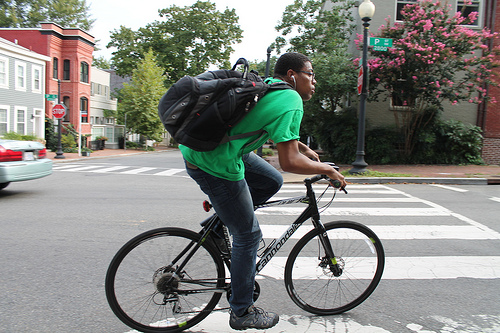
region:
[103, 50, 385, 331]
Boy riding bicycle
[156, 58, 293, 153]
Backpack on the boy's back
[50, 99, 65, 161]
Stop sign on curb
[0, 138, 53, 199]
Rear end of car going down the street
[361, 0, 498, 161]
Pink flowering plant by sidewalk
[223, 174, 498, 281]
White lines designating crosswalk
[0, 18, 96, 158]
Pink building next to grey building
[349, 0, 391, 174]
Street lamp with street sign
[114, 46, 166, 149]
Tree along the curb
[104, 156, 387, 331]
Black bike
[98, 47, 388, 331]
Male riding a bike on the road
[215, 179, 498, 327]
Crosswalk the male is driving over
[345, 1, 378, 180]
Old fashioned street lamp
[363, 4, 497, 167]
Pink flowering tree next to the building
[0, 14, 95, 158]
Red brick building on the left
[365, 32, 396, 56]
Green street sign with P on it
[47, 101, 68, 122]
Stop sign on the left side of the road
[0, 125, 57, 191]
Back of a silver car on the street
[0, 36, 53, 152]
Grey 2 story building with white trim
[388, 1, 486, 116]
Three windows behind the flowering pink tree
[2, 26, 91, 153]
a large red colored building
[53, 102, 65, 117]
a red and white STOP sign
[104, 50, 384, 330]
a guy riding a bicycle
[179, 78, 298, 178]
a green short sleeve shirt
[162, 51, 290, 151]
a black and dark grey bookbag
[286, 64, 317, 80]
a pair of corrective glasses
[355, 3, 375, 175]
a street light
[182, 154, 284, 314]
a pair of blue jeans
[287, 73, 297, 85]
a white earbud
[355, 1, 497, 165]
a small tree with pink blooms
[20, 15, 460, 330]
A person is riding a bicycle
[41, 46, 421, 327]
A person is in the city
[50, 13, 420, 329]
The man is going to school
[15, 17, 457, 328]
A man is going to work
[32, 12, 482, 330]
A man is wearing a backpack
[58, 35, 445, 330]
A man is wearing a green shirt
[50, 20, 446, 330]
A man is riding safely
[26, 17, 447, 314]
A man is enjoying his day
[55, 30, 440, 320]
A man is out in the daytime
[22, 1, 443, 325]
The man is riding home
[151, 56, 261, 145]
The boy is carrying a backpack.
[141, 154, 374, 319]
Boy is riding bike.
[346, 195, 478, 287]
White lines in the street.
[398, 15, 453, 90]
Pink flowers on the tree.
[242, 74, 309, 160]
The shirt is green.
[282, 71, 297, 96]
The boy is wearing earplugs.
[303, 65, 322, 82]
The boy is wearing glasses.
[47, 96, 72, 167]
Stop sign on the corner.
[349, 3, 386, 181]
Street light on the sidewalk.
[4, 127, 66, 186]
Car driving down street.